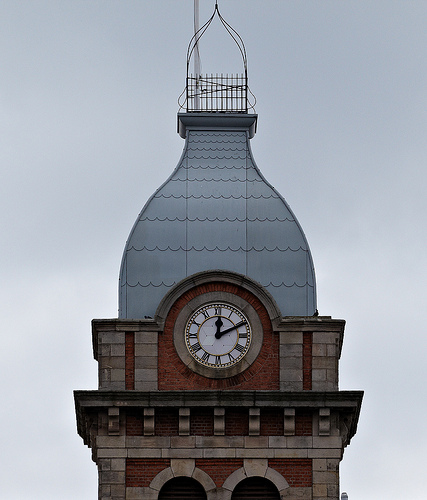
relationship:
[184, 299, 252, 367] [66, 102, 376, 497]
clock on buildings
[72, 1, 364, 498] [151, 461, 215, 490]
building has arch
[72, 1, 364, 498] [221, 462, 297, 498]
building has arch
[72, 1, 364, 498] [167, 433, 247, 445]
building has rust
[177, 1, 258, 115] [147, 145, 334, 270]
top on roof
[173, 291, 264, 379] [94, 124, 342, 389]
clock on tower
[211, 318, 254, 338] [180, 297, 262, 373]
hand on clock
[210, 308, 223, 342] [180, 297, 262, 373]
hand on clock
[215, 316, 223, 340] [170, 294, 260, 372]
hand on clock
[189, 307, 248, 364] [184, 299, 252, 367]
numbers on clock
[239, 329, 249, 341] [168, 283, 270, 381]
3 on clock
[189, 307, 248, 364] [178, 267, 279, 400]
numbers on clock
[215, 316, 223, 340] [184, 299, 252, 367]
hand on clock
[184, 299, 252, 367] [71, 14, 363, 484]
clock on tower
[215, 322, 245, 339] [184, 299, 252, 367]
hand on clock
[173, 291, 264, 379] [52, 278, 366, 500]
clock on tower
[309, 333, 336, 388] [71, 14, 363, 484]
bricks on tower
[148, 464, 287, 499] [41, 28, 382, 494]
arches of building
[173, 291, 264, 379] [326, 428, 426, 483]
clock on water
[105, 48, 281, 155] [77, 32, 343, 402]
arches on tower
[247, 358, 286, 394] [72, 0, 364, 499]
bricks on building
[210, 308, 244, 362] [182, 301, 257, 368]
numbers on clock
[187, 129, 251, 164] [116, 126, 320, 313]
waved grooves on top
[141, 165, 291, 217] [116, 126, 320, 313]
waved grooves on top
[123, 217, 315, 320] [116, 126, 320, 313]
waved grooves on top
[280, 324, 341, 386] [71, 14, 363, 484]
pillars on tower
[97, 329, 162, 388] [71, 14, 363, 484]
pillars on tower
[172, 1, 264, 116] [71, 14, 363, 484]
top of tower